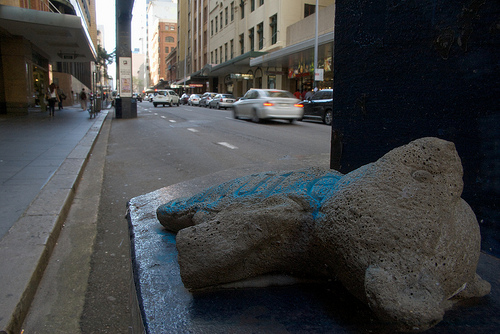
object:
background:
[132, 79, 236, 113]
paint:
[161, 171, 359, 218]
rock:
[157, 137, 496, 333]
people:
[45, 96, 58, 116]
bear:
[154, 137, 491, 334]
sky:
[94, 0, 149, 89]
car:
[199, 92, 218, 108]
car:
[179, 93, 190, 105]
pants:
[48, 106, 54, 115]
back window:
[259, 90, 296, 98]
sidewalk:
[0, 95, 109, 334]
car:
[296, 87, 333, 125]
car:
[232, 87, 305, 123]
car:
[209, 94, 237, 109]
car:
[153, 89, 181, 107]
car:
[187, 94, 202, 106]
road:
[16, 95, 331, 332]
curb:
[0, 111, 109, 333]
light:
[263, 103, 274, 107]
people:
[79, 88, 88, 111]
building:
[176, 0, 335, 101]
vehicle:
[147, 93, 158, 103]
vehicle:
[131, 93, 142, 102]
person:
[47, 82, 60, 108]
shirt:
[47, 87, 57, 98]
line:
[161, 116, 167, 119]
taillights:
[293, 104, 303, 108]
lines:
[217, 141, 239, 151]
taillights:
[262, 102, 273, 106]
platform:
[125, 163, 495, 334]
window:
[263, 90, 295, 98]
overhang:
[0, 0, 96, 65]